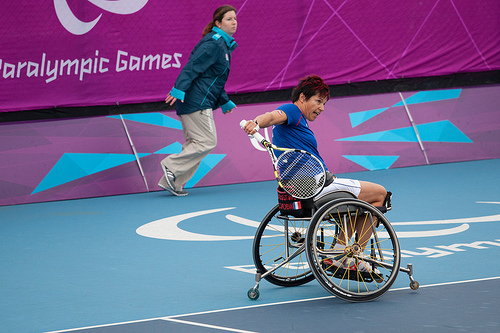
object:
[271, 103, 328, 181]
shirt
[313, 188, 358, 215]
part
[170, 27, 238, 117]
jacket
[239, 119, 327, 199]
racket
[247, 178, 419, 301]
wheelchair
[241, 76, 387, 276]
woman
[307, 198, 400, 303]
wheel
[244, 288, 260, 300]
stabilizing wheel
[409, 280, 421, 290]
stabilizing wheel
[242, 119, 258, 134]
hand